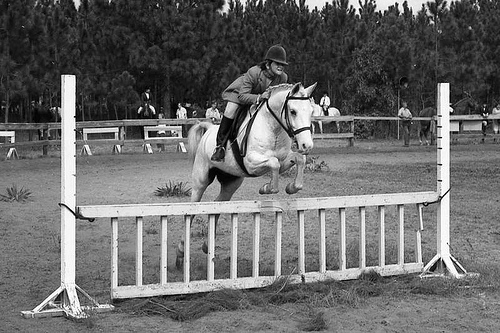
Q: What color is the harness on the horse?
A: Black.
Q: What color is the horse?
A: White.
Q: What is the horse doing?
A: Jumping.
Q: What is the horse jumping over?
A: Fence.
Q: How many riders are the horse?
A: One.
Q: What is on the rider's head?
A: Helmet.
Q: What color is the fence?
A: White.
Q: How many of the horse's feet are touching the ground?
A: Zero.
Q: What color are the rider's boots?
A: Black.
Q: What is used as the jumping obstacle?
A: Railings.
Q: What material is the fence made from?
A: Wood.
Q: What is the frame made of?
A: Wood.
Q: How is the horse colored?
A: White.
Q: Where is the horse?
A: Jumping over the railings.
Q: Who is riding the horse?
A: A woman.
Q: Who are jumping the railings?
A: A horse and rider.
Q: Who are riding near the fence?
A: Other horse riders.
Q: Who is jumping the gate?
A: The horse.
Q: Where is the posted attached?
A: To the gate.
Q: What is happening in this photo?
A: A horse is jumping over an obstacle.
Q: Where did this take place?
A: In a riding rink.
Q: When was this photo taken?
A: At the beginning of the jump.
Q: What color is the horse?
A: White.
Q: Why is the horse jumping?
A: This is a competition.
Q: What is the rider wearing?
A: A helmet and boots.